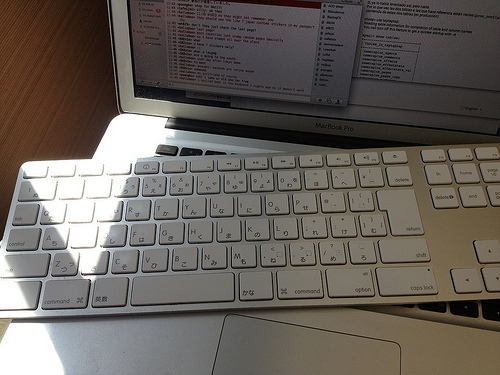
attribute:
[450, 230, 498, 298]
buttons — three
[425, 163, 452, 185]
keyboard button — 9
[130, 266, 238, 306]
spacebar — white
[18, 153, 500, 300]
keyboard — white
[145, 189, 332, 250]
letters — black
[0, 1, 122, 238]
table — wooden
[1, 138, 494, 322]
keyboard — white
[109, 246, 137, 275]
key — white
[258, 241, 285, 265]
key — white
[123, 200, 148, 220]
key — white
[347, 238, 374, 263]
key — white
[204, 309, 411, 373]
mousepad — white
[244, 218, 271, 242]
key — white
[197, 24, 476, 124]
screen — white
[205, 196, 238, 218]
key — white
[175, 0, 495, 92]
words — black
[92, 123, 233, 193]
buttons — black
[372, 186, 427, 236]
button — large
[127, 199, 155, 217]
white — key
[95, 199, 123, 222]
key — white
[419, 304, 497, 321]
buttons — black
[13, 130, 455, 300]
keyboard — silver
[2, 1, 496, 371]
laptop — on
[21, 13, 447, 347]
laptop — open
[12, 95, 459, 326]
keyboard — silver and white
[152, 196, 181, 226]
key — white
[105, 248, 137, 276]
key — white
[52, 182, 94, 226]
key — white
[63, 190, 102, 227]
key — white